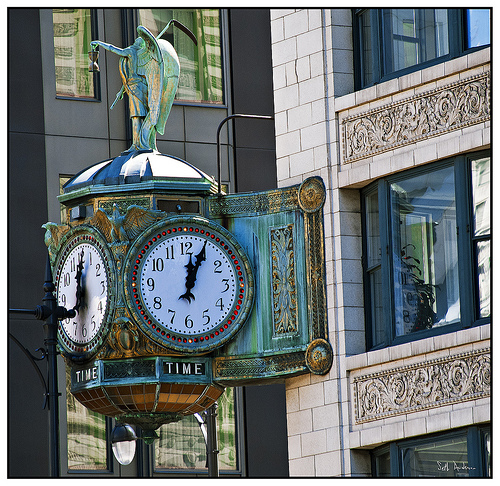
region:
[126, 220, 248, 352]
clock's face is white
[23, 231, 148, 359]
clock's face is white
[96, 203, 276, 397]
clock's face is white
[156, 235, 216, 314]
clock's hands are black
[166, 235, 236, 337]
clock's hands are black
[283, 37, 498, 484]
the house has windows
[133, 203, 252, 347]
the clock is round in shape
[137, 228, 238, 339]
the face is white in colour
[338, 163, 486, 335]
the windows are closed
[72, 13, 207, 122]
the clock has a sculpture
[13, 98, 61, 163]
the wall is grey in colour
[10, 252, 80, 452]
the post is black in colour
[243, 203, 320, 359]
the clock is green in colour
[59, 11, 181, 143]
the sculpture has wings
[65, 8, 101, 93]
the window has green curtains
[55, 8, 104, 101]
window on tall building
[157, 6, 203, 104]
window on tall building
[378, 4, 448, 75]
window on tall building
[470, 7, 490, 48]
window on tall building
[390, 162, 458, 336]
window on tall building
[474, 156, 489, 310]
window on tall building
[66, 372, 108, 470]
window on tall building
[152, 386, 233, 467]
window on tall building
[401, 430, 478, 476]
window on tall building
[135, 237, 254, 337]
clock with white face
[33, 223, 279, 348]
clocks on a colorful pole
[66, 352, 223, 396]
TIME written under each clock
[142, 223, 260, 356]
red dots around the clock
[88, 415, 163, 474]
light under the clock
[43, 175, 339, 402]
blue, green, orange all missed together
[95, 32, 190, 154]
statue on top of clocks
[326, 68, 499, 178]
design between the windows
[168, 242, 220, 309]
hands on clock are black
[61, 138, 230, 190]
blue on top of the clock and under the statue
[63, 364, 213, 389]
TIME written in white